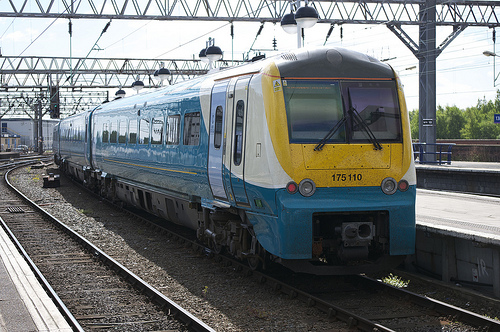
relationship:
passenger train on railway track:
[49, 43, 420, 283] [246, 260, 498, 330]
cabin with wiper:
[225, 44, 415, 264] [310, 109, 353, 153]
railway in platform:
[420, 140, 476, 192] [414, 155, 499, 175]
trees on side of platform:
[406, 100, 497, 145] [412, 126, 495, 246]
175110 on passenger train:
[326, 169, 364, 183] [49, 43, 420, 283]